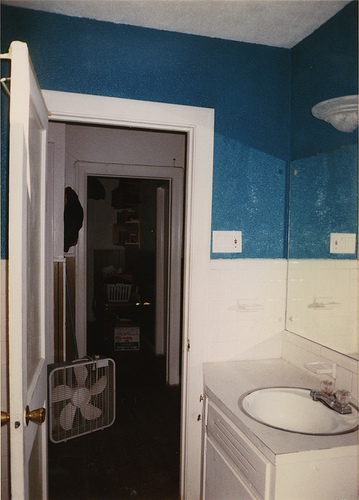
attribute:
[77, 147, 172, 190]
casing — top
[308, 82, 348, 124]
reflection — light fixture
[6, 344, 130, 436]
fan — box, white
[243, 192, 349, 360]
mirror — wall, reflection, large, above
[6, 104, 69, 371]
door — white, whit, gold, frame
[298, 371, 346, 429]
faucet — silver, handle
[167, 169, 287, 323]
wall — blue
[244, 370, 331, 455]
sink — white, qwhite, silver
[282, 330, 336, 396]
soap — white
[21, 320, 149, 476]
box — fan, under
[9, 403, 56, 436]
handle — door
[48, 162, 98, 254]
garment — hanging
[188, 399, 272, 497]
cabinet — white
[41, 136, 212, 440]
doorway — open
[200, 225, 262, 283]
outlet — electrical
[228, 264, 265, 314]
tile — white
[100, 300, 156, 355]
basket — white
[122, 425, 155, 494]
floor — dark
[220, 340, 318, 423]
plate — strike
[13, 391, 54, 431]
knob — door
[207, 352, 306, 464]
top — white